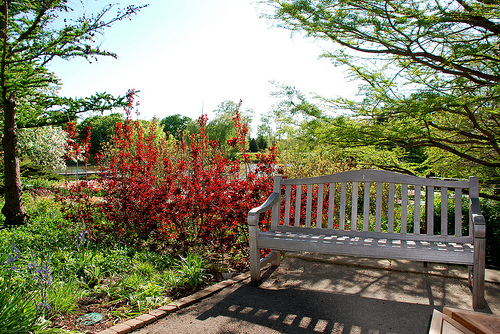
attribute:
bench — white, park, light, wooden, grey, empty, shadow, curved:
[250, 156, 489, 301]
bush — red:
[103, 114, 230, 221]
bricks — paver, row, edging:
[147, 295, 206, 332]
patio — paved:
[214, 205, 336, 329]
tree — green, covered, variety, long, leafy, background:
[279, 68, 457, 169]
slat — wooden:
[313, 182, 386, 236]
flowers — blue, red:
[7, 248, 92, 331]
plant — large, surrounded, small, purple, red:
[97, 83, 235, 205]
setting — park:
[55, 96, 494, 286]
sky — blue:
[112, 6, 368, 127]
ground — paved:
[177, 265, 355, 332]